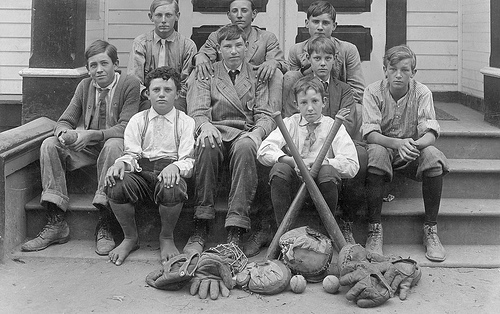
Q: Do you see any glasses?
A: No, there are no glasses.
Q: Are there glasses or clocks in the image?
A: No, there are no glasses or clocks.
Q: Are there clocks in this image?
A: No, there are no clocks.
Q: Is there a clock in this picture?
A: No, there are no clocks.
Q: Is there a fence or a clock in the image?
A: No, there are no clocks or fences.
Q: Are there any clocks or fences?
A: No, there are no clocks or fences.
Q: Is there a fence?
A: No, there are no fences.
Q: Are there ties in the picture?
A: Yes, there is a tie.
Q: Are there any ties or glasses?
A: Yes, there is a tie.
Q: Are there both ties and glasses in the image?
A: No, there is a tie but no glasses.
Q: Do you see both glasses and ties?
A: No, there is a tie but no glasses.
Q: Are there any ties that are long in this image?
A: Yes, there is a long tie.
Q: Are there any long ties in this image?
A: Yes, there is a long tie.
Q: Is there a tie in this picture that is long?
A: Yes, there is a tie that is long.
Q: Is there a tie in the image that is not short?
A: Yes, there is a long tie.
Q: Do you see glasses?
A: No, there are no glasses.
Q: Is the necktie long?
A: Yes, the necktie is long.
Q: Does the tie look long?
A: Yes, the tie is long.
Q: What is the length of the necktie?
A: The necktie is long.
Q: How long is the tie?
A: The tie is long.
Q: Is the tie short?
A: No, the tie is long.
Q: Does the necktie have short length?
A: No, the necktie is long.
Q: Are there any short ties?
A: No, there is a tie but it is long.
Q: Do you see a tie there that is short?
A: No, there is a tie but it is long.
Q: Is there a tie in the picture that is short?
A: No, there is a tie but it is long.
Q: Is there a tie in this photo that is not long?
A: No, there is a tie but it is long.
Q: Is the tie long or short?
A: The tie is long.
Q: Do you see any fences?
A: No, there are no fences.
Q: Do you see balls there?
A: Yes, there is a ball.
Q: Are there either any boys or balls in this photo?
A: Yes, there is a ball.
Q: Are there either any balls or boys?
A: Yes, there is a ball.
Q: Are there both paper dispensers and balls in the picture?
A: No, there is a ball but no paper dispensers.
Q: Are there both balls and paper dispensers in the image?
A: No, there is a ball but no paper dispensers.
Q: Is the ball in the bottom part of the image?
A: Yes, the ball is in the bottom of the image.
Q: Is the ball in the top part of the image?
A: No, the ball is in the bottom of the image.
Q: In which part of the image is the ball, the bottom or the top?
A: The ball is in the bottom of the image.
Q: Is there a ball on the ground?
A: Yes, there is a ball on the ground.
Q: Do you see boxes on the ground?
A: No, there is a ball on the ground.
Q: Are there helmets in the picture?
A: No, there are no helmets.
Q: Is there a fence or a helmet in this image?
A: No, there are no helmets or fences.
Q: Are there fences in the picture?
A: No, there are no fences.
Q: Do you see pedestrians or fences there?
A: No, there are no fences or pedestrians.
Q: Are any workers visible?
A: No, there are no workers.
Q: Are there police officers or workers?
A: No, there are no workers or police officers.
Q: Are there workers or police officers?
A: No, there are no workers or police officers.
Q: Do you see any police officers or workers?
A: No, there are no workers or police officers.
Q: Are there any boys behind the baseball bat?
A: Yes, there is a boy behind the baseball bat.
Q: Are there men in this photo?
A: No, there are no men.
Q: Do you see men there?
A: No, there are no men.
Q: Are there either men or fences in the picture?
A: No, there are no men or fences.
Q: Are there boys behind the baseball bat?
A: Yes, there is a boy behind the baseball bat.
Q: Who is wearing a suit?
A: The boy is wearing a suit.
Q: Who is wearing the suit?
A: The boy is wearing a suit.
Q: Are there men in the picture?
A: No, there are no men.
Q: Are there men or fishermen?
A: No, there are no men or fishermen.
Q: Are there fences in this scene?
A: No, there are no fences.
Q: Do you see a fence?
A: No, there are no fences.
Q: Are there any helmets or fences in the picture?
A: No, there are no fences or helmets.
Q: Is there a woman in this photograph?
A: No, there are no women.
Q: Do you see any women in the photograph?
A: No, there are no women.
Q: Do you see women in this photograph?
A: No, there are no women.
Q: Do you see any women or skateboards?
A: No, there are no women or skateboards.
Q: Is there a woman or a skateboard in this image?
A: No, there are no women or skateboards.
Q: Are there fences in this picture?
A: No, there are no fences.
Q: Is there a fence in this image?
A: No, there are no fences.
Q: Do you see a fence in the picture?
A: No, there are no fences.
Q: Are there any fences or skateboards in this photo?
A: No, there are no fences or skateboards.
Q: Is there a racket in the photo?
A: No, there are no rackets.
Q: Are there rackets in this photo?
A: No, there are no rackets.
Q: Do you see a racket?
A: No, there are no rackets.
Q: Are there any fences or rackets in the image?
A: No, there are no rackets or fences.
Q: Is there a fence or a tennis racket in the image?
A: No, there are no rackets or fences.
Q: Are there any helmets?
A: No, there are no helmets.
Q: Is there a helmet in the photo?
A: No, there are no helmets.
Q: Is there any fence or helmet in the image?
A: No, there are no helmets or fences.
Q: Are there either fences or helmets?
A: No, there are no helmets or fences.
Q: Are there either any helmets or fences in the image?
A: No, there are no helmets or fences.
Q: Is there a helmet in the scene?
A: No, there are no helmets.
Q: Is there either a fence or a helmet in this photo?
A: No, there are no helmets or fences.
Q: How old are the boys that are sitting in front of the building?
A: The boys are young.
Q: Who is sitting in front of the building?
A: The boys are sitting in front of the building.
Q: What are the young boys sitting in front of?
A: The boys are sitting in front of the building.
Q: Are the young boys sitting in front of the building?
A: Yes, the boys are sitting in front of the building.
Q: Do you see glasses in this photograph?
A: No, there are no glasses.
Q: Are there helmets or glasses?
A: No, there are no glasses or helmets.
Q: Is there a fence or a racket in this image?
A: No, there are no fences or rackets.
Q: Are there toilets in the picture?
A: No, there are no toilets.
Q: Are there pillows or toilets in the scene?
A: No, there are no toilets or pillows.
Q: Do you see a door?
A: Yes, there is a door.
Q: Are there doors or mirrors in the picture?
A: Yes, there is a door.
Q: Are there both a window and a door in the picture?
A: No, there is a door but no windows.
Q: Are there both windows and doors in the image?
A: No, there is a door but no windows.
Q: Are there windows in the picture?
A: No, there are no windows.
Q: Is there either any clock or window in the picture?
A: No, there are no windows or clocks.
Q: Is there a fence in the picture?
A: No, there are no fences.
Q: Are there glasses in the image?
A: No, there are no glasses.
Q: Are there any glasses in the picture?
A: No, there are no glasses.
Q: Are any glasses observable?
A: No, there are no glasses.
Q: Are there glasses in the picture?
A: No, there are no glasses.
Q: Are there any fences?
A: No, there are no fences.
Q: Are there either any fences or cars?
A: No, there are no fences or cars.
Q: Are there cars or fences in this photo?
A: No, there are no fences or cars.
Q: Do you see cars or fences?
A: No, there are no fences or cars.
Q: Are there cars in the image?
A: No, there are no cars.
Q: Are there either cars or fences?
A: No, there are no cars or fences.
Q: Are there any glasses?
A: No, there are no glasses.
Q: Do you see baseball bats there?
A: Yes, there is a baseball bat.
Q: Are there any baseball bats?
A: Yes, there is a baseball bat.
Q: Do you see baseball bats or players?
A: Yes, there is a baseball bat.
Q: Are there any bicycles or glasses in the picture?
A: No, there are no glasses or bicycles.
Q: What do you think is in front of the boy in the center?
A: The baseball bat is in front of the boy.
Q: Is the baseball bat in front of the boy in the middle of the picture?
A: Yes, the baseball bat is in front of the boy.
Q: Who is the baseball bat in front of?
A: The baseball bat is in front of the boy.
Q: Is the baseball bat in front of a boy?
A: Yes, the baseball bat is in front of a boy.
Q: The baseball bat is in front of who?
A: The baseball bat is in front of the boy.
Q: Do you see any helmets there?
A: No, there are no helmets.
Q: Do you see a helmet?
A: No, there are no helmets.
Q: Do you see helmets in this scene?
A: No, there are no helmets.